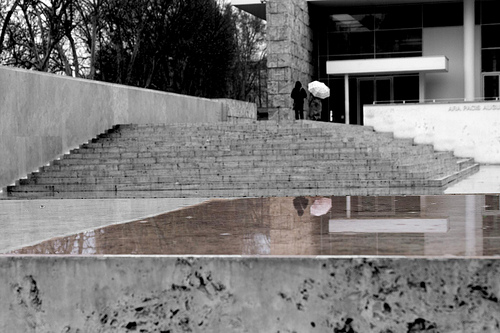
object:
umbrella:
[306, 79, 331, 99]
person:
[291, 81, 307, 122]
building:
[231, 2, 498, 116]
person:
[310, 83, 323, 120]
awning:
[326, 55, 449, 76]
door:
[359, 77, 375, 123]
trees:
[76, 3, 105, 75]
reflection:
[291, 197, 308, 216]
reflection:
[309, 196, 334, 217]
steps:
[84, 144, 364, 155]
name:
[449, 105, 500, 112]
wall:
[360, 101, 500, 165]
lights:
[328, 14, 356, 23]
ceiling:
[320, 10, 425, 49]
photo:
[2, 1, 499, 333]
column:
[265, 1, 315, 119]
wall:
[2, 63, 227, 194]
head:
[294, 80, 302, 88]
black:
[294, 90, 303, 109]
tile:
[17, 195, 499, 254]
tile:
[3, 199, 215, 253]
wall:
[219, 98, 259, 124]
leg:
[300, 109, 303, 119]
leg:
[295, 110, 299, 119]